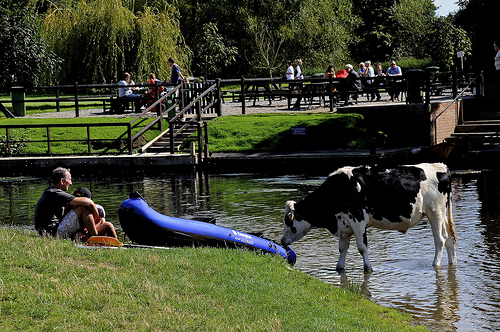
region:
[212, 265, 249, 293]
grass on the ground.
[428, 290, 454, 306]
reflection in the water.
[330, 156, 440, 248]
cow in the water.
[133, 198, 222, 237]
raft near the water.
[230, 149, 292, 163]
walkway near the water.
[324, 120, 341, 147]
shade on the grass.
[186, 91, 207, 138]
railing near the stairs.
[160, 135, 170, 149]
steps down the hill.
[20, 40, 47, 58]
leaves on the trees.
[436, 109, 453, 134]
wall made of bricks.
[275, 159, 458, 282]
black and white cow in water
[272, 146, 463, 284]
black and white cow standing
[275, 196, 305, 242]
black and white head of cow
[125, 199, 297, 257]
blue raft on grass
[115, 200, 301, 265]
blue inflatable raft on grass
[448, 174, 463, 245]
white and brown tail of cow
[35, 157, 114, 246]
people sitting on grass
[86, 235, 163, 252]
brown and black oar laying on grass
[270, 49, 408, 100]
people sitting at picnic tables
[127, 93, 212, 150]
wooden stairs leading to water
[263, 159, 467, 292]
a cow standing in water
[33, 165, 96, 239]
a man sitting in grass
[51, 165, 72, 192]
the head of a man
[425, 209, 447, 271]
the leg of a cow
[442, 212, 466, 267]
the leg of a cow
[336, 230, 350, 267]
the leg of a cow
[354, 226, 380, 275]
the leg of a cow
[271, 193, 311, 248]
the head of a cow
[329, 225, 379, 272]
the front legs of a cow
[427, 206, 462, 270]
the rear legs of a cow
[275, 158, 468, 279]
A black and white cow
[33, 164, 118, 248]
A man sitting in the grass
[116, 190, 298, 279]
A blue canoe near the water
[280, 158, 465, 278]
A cow standing in water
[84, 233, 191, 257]
A black and yellow canoe paddle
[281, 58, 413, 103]
People sitting at a table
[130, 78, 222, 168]
A wooden bridge with railings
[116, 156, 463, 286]
A cow smelling a canoe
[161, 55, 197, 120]
A man leaning against a wooden railing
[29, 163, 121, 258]
A man wearing swimming trunks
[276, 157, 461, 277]
Cow standing in water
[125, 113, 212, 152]
Wooden stairway in park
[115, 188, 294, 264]
Blue inflatable raft on shore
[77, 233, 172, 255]
Orange bladed raft paddle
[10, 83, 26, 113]
Green trash can in park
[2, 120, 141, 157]
Wooden rail fence along shoreline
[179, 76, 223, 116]
Wooden picket gate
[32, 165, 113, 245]
Man seated on shore line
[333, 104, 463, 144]
Brick retaining wall on shoreline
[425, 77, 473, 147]
Metal stairway hand rail